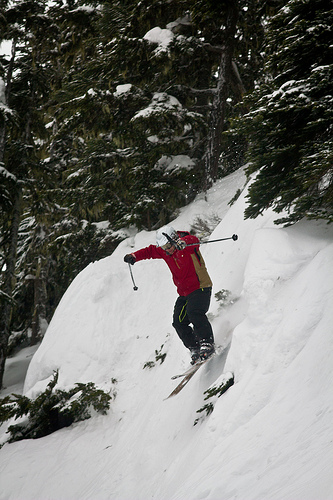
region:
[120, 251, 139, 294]
a man holding a ski pole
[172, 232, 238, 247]
a man holding a ski pole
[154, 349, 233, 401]
a man in brown skis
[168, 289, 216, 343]
a man in black pants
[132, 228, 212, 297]
a man in a red and gold jacket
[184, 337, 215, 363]
a man with black boots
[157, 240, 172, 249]
a man with goggles for snow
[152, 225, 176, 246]
a man with a white helmet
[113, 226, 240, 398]
a man skiing down a hill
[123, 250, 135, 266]
a man with black gloves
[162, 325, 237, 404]
Man on skis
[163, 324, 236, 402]
Man is on skis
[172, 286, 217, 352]
Man wearing pants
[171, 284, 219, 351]
Man is wearing pants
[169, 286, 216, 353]
Man wearing black pants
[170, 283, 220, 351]
Man is wearing black pants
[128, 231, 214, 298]
Man wearing a jacket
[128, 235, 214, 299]
Man is wearing a jacket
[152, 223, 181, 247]
Man wearing a helmet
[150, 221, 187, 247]
Man wearing a white helmet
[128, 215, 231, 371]
man is on top of a hill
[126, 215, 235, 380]
the man is skiing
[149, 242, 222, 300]
the jacket is red in color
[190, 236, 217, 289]
the jacket has some yellow stripes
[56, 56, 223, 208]
trees are adjacent to the hill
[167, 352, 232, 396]
the skiing bpards are covered of snow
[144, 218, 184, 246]
the helmet is white in color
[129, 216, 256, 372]
the man has skiing stick in his hands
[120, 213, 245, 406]
Skier on the mountain.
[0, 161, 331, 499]
Snow covering the ground.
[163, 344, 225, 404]
Skis on the feet.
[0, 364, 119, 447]
Bush in the snow.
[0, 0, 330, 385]
Tree in the background.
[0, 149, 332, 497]
Mountain in the landscape.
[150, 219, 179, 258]
White helmet on the head.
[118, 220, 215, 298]
Red jacket on the man.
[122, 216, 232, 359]
Black pants on the boy.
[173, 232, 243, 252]
Ski pole in the hand.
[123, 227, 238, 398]
Man skiing in a red jacket.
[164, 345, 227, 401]
Two skis and shoes on a man.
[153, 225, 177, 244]
White hat on a man skiing.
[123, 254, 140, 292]
Pole in the skier's right hand.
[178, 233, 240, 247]
Pole in the skier's left hand.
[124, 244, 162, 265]
Right arm of a man skiing.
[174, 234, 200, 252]
Left arm of a man skiing.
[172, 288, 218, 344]
Legs in black pants of a man skiing.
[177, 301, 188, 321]
Green spot on skier's right leg.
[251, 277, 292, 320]
white snow on hill side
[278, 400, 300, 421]
white snow on hill side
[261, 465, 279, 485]
white snow on hill side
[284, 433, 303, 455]
white snow on hill side